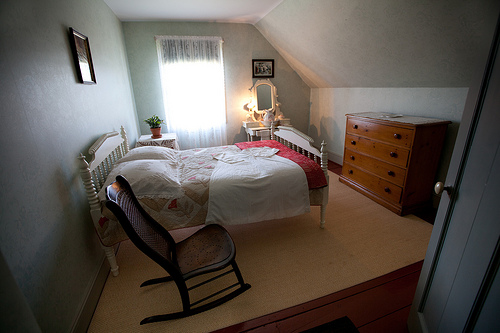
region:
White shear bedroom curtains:
[150, 31, 227, 146]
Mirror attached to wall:
[245, 77, 275, 117]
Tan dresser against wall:
[335, 110, 481, 217]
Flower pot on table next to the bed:
[140, 115, 162, 138]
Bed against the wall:
[78, 126, 330, 237]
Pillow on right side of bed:
[101, 157, 178, 194]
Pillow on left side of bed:
[120, 142, 178, 158]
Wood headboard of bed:
[76, 125, 128, 202]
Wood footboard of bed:
[267, 117, 327, 232]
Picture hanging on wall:
[61, 23, 97, 86]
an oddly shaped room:
[26, 2, 431, 313]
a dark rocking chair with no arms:
[99, 168, 256, 324]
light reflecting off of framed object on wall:
[59, 26, 104, 89]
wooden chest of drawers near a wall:
[333, 88, 449, 232]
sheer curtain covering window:
[161, 29, 230, 156]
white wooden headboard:
[77, 126, 128, 276]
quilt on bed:
[111, 139, 240, 234]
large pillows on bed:
[98, 134, 184, 211]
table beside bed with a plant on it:
[132, 112, 217, 208]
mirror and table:
[236, 75, 291, 147]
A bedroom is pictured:
[45, 13, 460, 302]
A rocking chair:
[101, 172, 255, 326]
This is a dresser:
[336, 102, 455, 216]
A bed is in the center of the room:
[76, 123, 344, 256]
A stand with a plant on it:
[136, 115, 180, 158]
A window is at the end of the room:
[153, 30, 234, 146]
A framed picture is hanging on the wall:
[63, 22, 113, 94]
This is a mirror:
[241, 80, 290, 114]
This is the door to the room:
[414, 18, 498, 331]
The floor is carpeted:
[254, 230, 367, 291]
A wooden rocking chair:
[90, 180, 258, 319]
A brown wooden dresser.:
[343, 108, 440, 218]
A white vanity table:
[240, 73, 298, 140]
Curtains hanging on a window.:
[152, 37, 237, 151]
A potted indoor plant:
[140, 115, 170, 141]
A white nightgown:
[203, 145, 319, 232]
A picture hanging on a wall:
[59, 24, 110, 92]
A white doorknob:
[428, 176, 454, 200]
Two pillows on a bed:
[102, 139, 180, 203]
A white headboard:
[62, 126, 133, 278]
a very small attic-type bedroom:
[53, 16, 443, 283]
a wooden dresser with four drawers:
[332, 112, 435, 217]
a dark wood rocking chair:
[89, 178, 253, 316]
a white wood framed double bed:
[83, 130, 335, 246]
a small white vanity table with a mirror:
[243, 84, 293, 144]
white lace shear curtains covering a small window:
[151, 33, 233, 143]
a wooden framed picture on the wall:
[66, 25, 100, 85]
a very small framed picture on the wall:
[248, 54, 280, 79]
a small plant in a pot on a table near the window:
[140, 117, 170, 136]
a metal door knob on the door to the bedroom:
[433, 182, 455, 193]